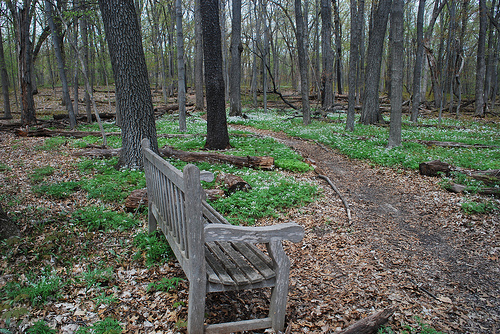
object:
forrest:
[0, 0, 498, 328]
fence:
[0, 81, 498, 122]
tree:
[94, 0, 162, 172]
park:
[1, 4, 494, 330]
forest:
[0, 0, 497, 332]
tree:
[387, 0, 407, 145]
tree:
[345, 0, 358, 130]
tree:
[294, 0, 311, 128]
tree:
[197, 0, 230, 149]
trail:
[227, 120, 498, 333]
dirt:
[2, 120, 500, 333]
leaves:
[287, 133, 497, 331]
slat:
[204, 245, 233, 286]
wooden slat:
[204, 206, 277, 280]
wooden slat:
[148, 162, 188, 258]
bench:
[141, 137, 304, 333]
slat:
[206, 241, 249, 285]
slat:
[206, 260, 219, 283]